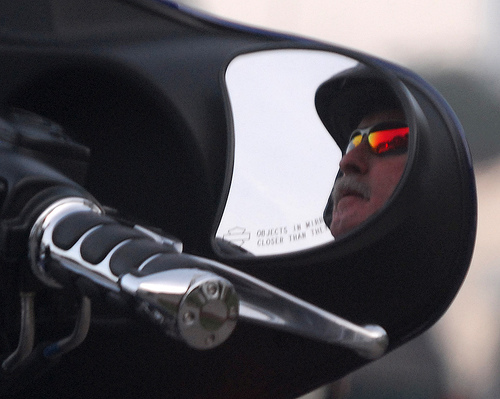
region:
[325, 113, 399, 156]
man wearing red sunglasses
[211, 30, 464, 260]
mirror on a motorcycle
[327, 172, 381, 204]
man with a mustache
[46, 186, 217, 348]
handle on a motorcycle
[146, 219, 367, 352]
brakes for a motorcycle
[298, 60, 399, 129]
man wearing a helmet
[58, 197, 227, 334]
black and chrome bike handle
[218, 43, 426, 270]
man reflection in the mirror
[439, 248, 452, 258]
part of a mirror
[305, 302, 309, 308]
part of an handle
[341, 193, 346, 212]
edge of a mirror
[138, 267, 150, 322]
part of a brake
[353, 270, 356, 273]
edge of a mirror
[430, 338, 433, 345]
side of a wall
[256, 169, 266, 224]
part of a mirror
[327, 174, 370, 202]
A gray mustache on the man's face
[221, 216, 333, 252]
Writing on the side mirror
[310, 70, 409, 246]
The rider's face reflected in the mirror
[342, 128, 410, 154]
A pair of colored sunglasses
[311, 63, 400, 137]
The tip of a black helmet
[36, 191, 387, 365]
A metal handlebar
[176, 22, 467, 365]
The side mirror on the motorcycle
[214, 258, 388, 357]
The metal brake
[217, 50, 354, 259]
The gray sky reflected in the mirror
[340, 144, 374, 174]
The man's nose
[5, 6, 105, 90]
this is black in colour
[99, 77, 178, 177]
this is black in colour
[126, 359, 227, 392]
this is black in colour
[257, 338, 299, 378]
this is black in colour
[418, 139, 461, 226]
this is black in colour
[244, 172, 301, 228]
this iswhite in colour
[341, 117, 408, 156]
this is a pair of glasses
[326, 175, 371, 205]
this is a persons mouth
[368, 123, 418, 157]
Reflective lense on sunglass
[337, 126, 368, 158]
Reflective lense on sunglass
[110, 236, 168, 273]
Black plastic grip pn handle bar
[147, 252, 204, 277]
Black plastic grip pn handle bar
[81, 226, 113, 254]
Black plastic grip pn handle bar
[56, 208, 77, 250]
Black plastic grip pn handle bar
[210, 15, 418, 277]
Large reflective mirror on bike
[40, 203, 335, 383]
Silver clutch on bike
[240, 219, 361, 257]
Black lettering on mirror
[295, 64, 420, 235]
Man wearing a black helmet